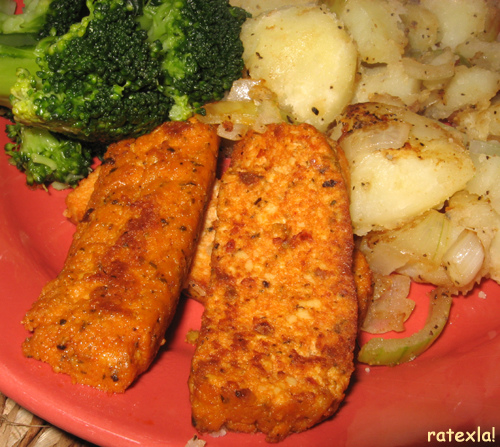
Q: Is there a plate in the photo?
A: Yes, there is a plate.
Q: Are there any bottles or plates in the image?
A: Yes, there is a plate.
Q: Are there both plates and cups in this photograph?
A: No, there is a plate but no cups.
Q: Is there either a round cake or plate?
A: Yes, there is a round plate.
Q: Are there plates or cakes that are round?
A: Yes, the plate is round.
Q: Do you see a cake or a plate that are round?
A: Yes, the plate is round.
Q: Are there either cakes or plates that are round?
A: Yes, the plate is round.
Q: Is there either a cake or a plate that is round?
A: Yes, the plate is round.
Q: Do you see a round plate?
A: Yes, there is a round plate.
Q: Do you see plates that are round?
A: Yes, there is a plate that is round.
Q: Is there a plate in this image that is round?
A: Yes, there is a plate that is round.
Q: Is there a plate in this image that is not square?
A: Yes, there is a round plate.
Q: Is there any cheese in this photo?
A: No, there is no cheese.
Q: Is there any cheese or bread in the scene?
A: No, there are no cheese or breads.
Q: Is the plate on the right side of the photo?
A: Yes, the plate is on the right of the image.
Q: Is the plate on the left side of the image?
A: No, the plate is on the right of the image.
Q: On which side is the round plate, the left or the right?
A: The plate is on the right of the image.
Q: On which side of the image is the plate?
A: The plate is on the right of the image.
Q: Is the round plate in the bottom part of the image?
A: Yes, the plate is in the bottom of the image.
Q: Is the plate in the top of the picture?
A: No, the plate is in the bottom of the image.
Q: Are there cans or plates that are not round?
A: No, there is a plate but it is round.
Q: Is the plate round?
A: Yes, the plate is round.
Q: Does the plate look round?
A: Yes, the plate is round.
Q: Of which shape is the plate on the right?
A: The plate is round.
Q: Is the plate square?
A: No, the plate is round.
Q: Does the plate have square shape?
A: No, the plate is round.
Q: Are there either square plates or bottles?
A: No, there is a plate but it is round.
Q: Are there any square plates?
A: No, there is a plate but it is round.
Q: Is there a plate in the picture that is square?
A: No, there is a plate but it is round.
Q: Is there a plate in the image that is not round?
A: No, there is a plate but it is round.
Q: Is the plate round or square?
A: The plate is round.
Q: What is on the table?
A: The plate is on the table.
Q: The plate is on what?
A: The plate is on the table.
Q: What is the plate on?
A: The plate is on the table.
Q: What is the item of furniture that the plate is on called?
A: The piece of furniture is a table.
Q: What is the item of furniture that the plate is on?
A: The piece of furniture is a table.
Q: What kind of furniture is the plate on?
A: The plate is on the table.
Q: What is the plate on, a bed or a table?
A: The plate is on a table.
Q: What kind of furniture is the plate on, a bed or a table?
A: The plate is on a table.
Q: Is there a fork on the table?
A: No, there is a plate on the table.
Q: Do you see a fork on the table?
A: No, there is a plate on the table.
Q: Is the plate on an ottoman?
A: No, the plate is on the table.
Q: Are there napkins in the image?
A: No, there are no napkins.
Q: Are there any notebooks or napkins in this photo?
A: No, there are no napkins or notebooks.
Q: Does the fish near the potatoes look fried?
A: Yes, the fish is fried.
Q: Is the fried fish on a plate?
A: Yes, the fish is on a plate.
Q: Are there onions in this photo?
A: Yes, there is an onion.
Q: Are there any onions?
A: Yes, there is an onion.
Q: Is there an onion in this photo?
A: Yes, there is an onion.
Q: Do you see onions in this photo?
A: Yes, there is an onion.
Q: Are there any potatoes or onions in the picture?
A: Yes, there is an onion.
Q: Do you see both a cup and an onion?
A: No, there is an onion but no cups.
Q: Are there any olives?
A: No, there are no olives.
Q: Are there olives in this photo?
A: No, there are no olives.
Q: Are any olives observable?
A: No, there are no olives.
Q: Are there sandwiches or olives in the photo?
A: No, there are no olives or sandwiches.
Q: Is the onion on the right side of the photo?
A: Yes, the onion is on the right of the image.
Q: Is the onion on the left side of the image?
A: No, the onion is on the right of the image.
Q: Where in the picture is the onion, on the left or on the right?
A: The onion is on the right of the image.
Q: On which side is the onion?
A: The onion is on the right of the image.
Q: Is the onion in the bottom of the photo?
A: Yes, the onion is in the bottom of the image.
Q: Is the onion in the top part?
A: No, the onion is in the bottom of the image.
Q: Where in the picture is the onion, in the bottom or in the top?
A: The onion is in the bottom of the image.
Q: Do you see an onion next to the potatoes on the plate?
A: Yes, there is an onion next to the potatoes.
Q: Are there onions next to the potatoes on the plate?
A: Yes, there is an onion next to the potatoes.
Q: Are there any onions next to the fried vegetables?
A: Yes, there is an onion next to the potatoes.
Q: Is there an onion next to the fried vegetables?
A: Yes, there is an onion next to the potatoes.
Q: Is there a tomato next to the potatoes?
A: No, there is an onion next to the potatoes.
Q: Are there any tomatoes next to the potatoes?
A: No, there is an onion next to the potatoes.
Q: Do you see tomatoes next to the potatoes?
A: No, there is an onion next to the potatoes.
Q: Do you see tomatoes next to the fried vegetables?
A: No, there is an onion next to the potatoes.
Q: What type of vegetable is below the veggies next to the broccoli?
A: The vegetable is an onion.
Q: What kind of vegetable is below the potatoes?
A: The vegetable is an onion.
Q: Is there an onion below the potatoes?
A: Yes, there is an onion below the potatoes.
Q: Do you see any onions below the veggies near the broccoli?
A: Yes, there is an onion below the potatoes.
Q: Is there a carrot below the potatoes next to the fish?
A: No, there is an onion below the potatoes.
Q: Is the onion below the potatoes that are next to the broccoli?
A: Yes, the onion is below the potatoes.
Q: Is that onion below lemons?
A: No, the onion is below the potatoes.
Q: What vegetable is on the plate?
A: The vegetable is an onion.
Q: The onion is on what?
A: The onion is on the plate.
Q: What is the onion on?
A: The onion is on the plate.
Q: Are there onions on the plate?
A: Yes, there is an onion on the plate.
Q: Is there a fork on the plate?
A: No, there is an onion on the plate.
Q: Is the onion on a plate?
A: Yes, the onion is on a plate.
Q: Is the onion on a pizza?
A: No, the onion is on a plate.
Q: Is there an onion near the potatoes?
A: Yes, there is an onion near the potatoes.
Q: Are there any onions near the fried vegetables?
A: Yes, there is an onion near the potatoes.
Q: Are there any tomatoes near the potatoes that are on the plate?
A: No, there is an onion near the potatoes.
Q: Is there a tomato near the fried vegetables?
A: No, there is an onion near the potatoes.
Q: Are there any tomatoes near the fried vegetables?
A: No, there is an onion near the potatoes.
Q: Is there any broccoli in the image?
A: Yes, there is broccoli.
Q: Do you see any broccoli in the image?
A: Yes, there is broccoli.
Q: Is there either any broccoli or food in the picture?
A: Yes, there is broccoli.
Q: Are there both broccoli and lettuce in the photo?
A: No, there is broccoli but no lettuce.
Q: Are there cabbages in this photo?
A: No, there are no cabbages.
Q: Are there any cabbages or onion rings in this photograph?
A: No, there are no cabbages or onion rings.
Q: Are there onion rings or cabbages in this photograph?
A: No, there are no cabbages or onion rings.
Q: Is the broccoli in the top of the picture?
A: Yes, the broccoli is in the top of the image.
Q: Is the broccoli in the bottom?
A: No, the broccoli is in the top of the image.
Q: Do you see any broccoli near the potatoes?
A: Yes, there is broccoli near the potatoes.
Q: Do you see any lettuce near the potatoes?
A: No, there is broccoli near the potatoes.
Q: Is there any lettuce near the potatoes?
A: No, there is broccoli near the potatoes.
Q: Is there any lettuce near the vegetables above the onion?
A: No, there is broccoli near the potatoes.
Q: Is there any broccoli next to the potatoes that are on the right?
A: Yes, there is broccoli next to the potatoes.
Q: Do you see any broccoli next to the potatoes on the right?
A: Yes, there is broccoli next to the potatoes.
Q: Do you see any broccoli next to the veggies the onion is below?
A: Yes, there is broccoli next to the potatoes.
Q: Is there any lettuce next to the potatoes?
A: No, there is broccoli next to the potatoes.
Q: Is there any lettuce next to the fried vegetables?
A: No, there is broccoli next to the potatoes.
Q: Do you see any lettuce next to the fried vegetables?
A: No, there is broccoli next to the potatoes.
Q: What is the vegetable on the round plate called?
A: The vegetable is broccoli.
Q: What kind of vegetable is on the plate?
A: The vegetable is broccoli.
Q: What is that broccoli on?
A: The broccoli is on the plate.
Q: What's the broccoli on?
A: The broccoli is on the plate.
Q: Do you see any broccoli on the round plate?
A: Yes, there is broccoli on the plate.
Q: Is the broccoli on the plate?
A: Yes, the broccoli is on the plate.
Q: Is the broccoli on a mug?
A: No, the broccoli is on the plate.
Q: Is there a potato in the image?
A: Yes, there are potatoes.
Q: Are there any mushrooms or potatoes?
A: Yes, there are potatoes.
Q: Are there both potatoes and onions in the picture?
A: Yes, there are both potatoes and an onion.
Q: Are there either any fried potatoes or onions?
A: Yes, there are fried potatoes.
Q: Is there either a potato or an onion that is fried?
A: Yes, the potatoes are fried.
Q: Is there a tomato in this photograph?
A: No, there are no tomatoes.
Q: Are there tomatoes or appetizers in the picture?
A: No, there are no tomatoes or appetizers.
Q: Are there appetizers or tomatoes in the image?
A: No, there are no tomatoes or appetizers.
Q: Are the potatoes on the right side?
A: Yes, the potatoes are on the right of the image.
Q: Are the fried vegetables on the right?
A: Yes, the potatoes are on the right of the image.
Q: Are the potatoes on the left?
A: No, the potatoes are on the right of the image.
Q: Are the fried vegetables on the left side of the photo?
A: No, the potatoes are on the right of the image.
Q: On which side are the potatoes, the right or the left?
A: The potatoes are on the right of the image.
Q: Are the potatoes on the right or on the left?
A: The potatoes are on the right of the image.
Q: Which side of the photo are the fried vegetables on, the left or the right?
A: The potatoes are on the right of the image.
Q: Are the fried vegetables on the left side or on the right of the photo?
A: The potatoes are on the right of the image.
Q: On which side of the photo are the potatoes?
A: The potatoes are on the right of the image.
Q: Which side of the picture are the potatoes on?
A: The potatoes are on the right of the image.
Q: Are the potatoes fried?
A: Yes, the potatoes are fried.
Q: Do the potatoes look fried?
A: Yes, the potatoes are fried.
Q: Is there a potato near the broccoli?
A: Yes, there are potatoes near the broccoli.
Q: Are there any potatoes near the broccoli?
A: Yes, there are potatoes near the broccoli.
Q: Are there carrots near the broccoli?
A: No, there are potatoes near the broccoli.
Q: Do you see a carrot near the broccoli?
A: No, there are potatoes near the broccoli.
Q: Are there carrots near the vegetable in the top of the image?
A: No, there are potatoes near the broccoli.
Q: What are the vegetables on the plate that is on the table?
A: The vegetables are potatoes.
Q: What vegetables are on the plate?
A: The vegetables are potatoes.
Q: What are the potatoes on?
A: The potatoes are on the plate.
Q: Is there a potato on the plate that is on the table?
A: Yes, there are potatoes on the plate.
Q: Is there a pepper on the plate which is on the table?
A: No, there are potatoes on the plate.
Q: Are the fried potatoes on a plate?
A: Yes, the potatoes are on a plate.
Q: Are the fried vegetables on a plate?
A: Yes, the potatoes are on a plate.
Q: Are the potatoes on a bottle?
A: No, the potatoes are on a plate.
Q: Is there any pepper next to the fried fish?
A: No, there are potatoes next to the fish.